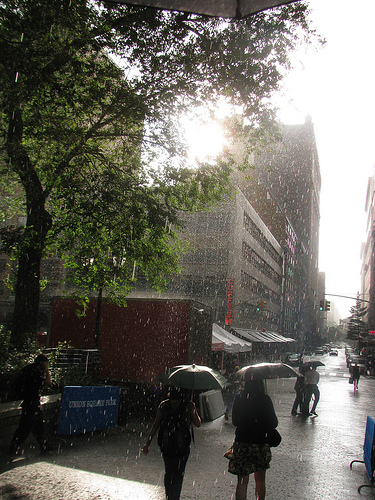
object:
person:
[351, 362, 359, 390]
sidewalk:
[1, 348, 373, 497]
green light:
[319, 307, 323, 310]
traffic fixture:
[319, 299, 330, 312]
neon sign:
[225, 279, 233, 325]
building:
[0, 0, 375, 498]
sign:
[48, 296, 190, 382]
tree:
[0, 0, 328, 353]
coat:
[232, 390, 278, 442]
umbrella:
[156, 364, 223, 444]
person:
[141, 387, 200, 500]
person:
[10, 354, 51, 453]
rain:
[0, 0, 375, 499]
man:
[304, 366, 320, 415]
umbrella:
[299, 361, 325, 371]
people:
[224, 380, 279, 499]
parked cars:
[315, 341, 365, 373]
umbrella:
[234, 362, 304, 394]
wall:
[0, 395, 62, 459]